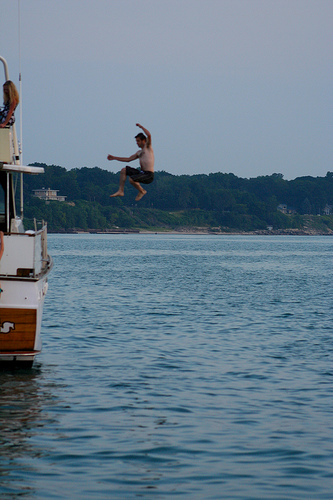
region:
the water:
[97, 296, 190, 482]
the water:
[167, 359, 219, 496]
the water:
[178, 395, 232, 488]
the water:
[185, 421, 216, 478]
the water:
[104, 338, 169, 466]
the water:
[168, 376, 199, 467]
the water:
[140, 374, 188, 483]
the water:
[159, 398, 203, 496]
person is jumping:
[91, 111, 164, 215]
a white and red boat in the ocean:
[0, 54, 60, 371]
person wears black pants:
[98, 114, 169, 212]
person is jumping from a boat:
[6, 57, 197, 399]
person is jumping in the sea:
[80, 88, 186, 323]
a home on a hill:
[26, 181, 81, 214]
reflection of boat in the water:
[6, 361, 71, 466]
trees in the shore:
[30, 158, 331, 235]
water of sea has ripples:
[60, 262, 329, 493]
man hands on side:
[101, 117, 162, 210]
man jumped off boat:
[89, 105, 194, 214]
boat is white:
[18, 251, 97, 380]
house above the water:
[28, 170, 76, 211]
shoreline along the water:
[113, 224, 292, 239]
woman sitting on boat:
[0, 74, 19, 155]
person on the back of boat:
[0, 223, 9, 258]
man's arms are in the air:
[100, 116, 188, 181]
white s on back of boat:
[4, 318, 15, 339]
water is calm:
[45, 270, 279, 386]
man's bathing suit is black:
[115, 156, 173, 197]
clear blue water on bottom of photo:
[60, 342, 202, 432]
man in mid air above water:
[111, 109, 210, 232]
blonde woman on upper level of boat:
[3, 78, 27, 129]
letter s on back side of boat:
[5, 318, 16, 347]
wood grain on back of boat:
[14, 313, 34, 353]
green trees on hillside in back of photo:
[196, 174, 234, 208]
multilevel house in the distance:
[33, 180, 82, 208]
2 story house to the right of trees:
[316, 196, 330, 223]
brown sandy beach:
[149, 226, 190, 241]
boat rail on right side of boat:
[24, 216, 54, 258]